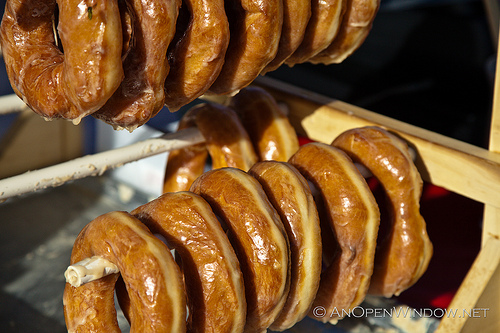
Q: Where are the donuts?
A: On pegs.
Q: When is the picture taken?
A: Day time.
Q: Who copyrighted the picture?
A: AnOpenWindow.NET.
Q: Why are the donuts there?
A: To eat.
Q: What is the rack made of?
A: Wood.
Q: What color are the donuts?
A: Brown.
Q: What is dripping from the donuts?
A: Sugar glaze.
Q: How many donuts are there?
A: 15.